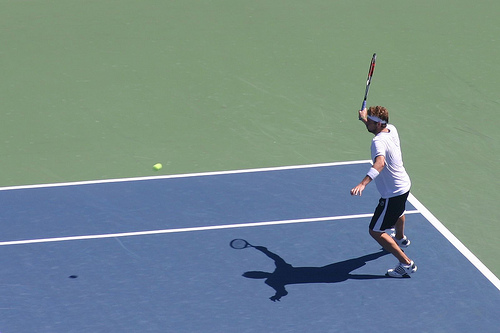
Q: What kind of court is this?
A: Tennis court.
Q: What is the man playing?
A: Tennis.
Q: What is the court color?
A: Blue.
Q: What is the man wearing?
A: Short and shirt.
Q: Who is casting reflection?
A: The man is.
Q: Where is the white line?
A: Inside court.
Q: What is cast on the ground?
A: Shadow.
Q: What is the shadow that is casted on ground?
A: Of person playing.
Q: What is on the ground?
A: Shadow.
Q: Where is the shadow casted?
A: On the ground.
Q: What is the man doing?
A: Playing tennis.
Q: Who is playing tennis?
A: The man.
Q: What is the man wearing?
A: White shirt and black shorts.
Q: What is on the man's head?
A: A headband.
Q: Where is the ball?
A: In the air.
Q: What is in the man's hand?
A: Tennis racket.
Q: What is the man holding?
A: Tennis racket.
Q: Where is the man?
A: Tennis court.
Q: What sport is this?
A: Tennis.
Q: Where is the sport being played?
A: Tennis court.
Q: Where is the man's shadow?
A: In front of him.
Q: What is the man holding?
A: Tennis racket.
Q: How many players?
A: One.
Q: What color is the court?
A: Blue.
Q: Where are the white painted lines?
A: Around the court.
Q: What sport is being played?
A: Tennis.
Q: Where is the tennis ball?
A: In the air.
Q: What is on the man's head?
A: Headband.